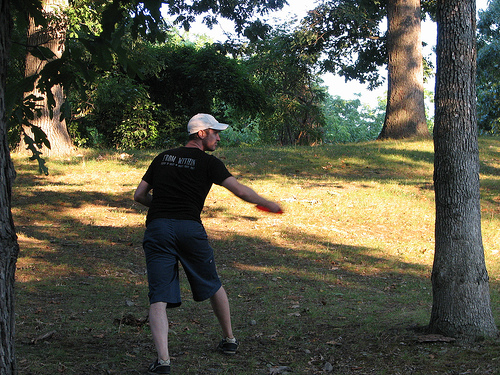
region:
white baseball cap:
[186, 114, 230, 134]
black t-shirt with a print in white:
[143, 147, 229, 214]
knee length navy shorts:
[141, 218, 223, 303]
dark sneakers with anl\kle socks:
[156, 334, 244, 372]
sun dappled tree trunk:
[381, 6, 428, 142]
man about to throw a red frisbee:
[248, 198, 290, 218]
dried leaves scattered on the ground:
[0, 261, 474, 373]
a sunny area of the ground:
[229, 173, 499, 260]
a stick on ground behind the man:
[23, 317, 63, 348]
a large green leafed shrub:
[129, 48, 275, 138]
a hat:
[189, 114, 227, 130]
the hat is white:
[187, 113, 219, 126]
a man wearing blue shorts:
[146, 227, 210, 281]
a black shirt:
[160, 181, 188, 208]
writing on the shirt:
[158, 151, 199, 172]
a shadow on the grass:
[241, 237, 317, 268]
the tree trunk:
[432, 162, 490, 337]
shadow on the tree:
[386, 78, 423, 136]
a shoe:
[221, 343, 237, 353]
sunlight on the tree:
[43, 122, 76, 159]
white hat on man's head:
[186, 112, 228, 132]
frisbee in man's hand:
[256, 201, 293, 218]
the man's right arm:
[215, 164, 289, 221]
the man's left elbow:
[126, 183, 146, 203]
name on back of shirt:
[160, 150, 197, 173]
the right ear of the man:
[196, 125, 211, 143]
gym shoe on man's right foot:
[212, 332, 246, 355]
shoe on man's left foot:
[147, 356, 182, 373]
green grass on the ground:
[359, 144, 384, 165]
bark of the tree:
[422, 0, 498, 339]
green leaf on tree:
[96, 84, 121, 103]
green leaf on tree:
[124, 117, 148, 142]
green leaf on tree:
[95, 58, 116, 70]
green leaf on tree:
[128, 56, 163, 78]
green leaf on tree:
[178, 71, 202, 90]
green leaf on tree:
[213, 51, 255, 105]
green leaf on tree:
[241, 103, 264, 137]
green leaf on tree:
[274, 81, 307, 123]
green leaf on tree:
[251, 48, 271, 69]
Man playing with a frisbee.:
[111, 90, 292, 367]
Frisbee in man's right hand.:
[249, 183, 289, 225]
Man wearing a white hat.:
[182, 107, 230, 152]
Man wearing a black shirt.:
[137, 138, 232, 217]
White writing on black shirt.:
[147, 143, 213, 216]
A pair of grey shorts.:
[126, 208, 230, 305]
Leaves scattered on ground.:
[20, 132, 468, 373]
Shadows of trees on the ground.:
[16, 93, 478, 366]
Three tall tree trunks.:
[7, 11, 496, 351]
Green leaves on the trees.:
[0, 5, 494, 108]